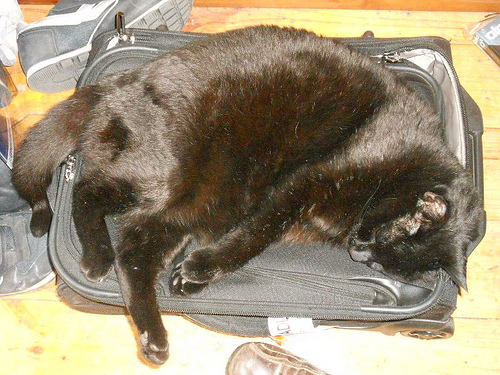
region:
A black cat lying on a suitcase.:
[11, 24, 483, 366]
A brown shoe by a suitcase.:
[225, 339, 329, 373]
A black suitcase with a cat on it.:
[46, 23, 484, 337]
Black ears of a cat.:
[418, 186, 468, 293]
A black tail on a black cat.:
[9, 83, 106, 235]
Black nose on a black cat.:
[347, 241, 372, 261]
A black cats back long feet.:
[69, 183, 171, 368]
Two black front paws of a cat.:
[169, 245, 225, 299]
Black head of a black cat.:
[348, 159, 485, 291]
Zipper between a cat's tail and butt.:
[62, 152, 76, 184]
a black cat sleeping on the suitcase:
[11, 25, 478, 366]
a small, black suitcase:
[45, 23, 488, 338]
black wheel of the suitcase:
[402, 316, 455, 340]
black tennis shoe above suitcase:
[14, 0, 196, 92]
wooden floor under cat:
[0, 0, 499, 372]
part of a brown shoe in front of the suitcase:
[224, 341, 333, 373]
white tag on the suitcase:
[266, 310, 316, 339]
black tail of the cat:
[13, 76, 105, 237]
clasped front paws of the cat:
[169, 246, 231, 293]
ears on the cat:
[419, 190, 468, 292]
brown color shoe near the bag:
[231, 333, 351, 374]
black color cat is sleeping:
[37, 53, 459, 311]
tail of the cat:
[11, 103, 69, 235]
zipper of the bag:
[115, 13, 129, 42]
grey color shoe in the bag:
[16, 0, 208, 80]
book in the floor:
[470, 10, 498, 52]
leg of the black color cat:
[83, 169, 170, 356]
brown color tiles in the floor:
[371, 7, 461, 22]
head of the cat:
[378, 155, 464, 290]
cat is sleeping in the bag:
[88, 23, 448, 288]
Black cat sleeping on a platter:
[10, 20, 459, 350]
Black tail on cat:
[0, 87, 72, 241]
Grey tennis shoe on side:
[9, 5, 106, 83]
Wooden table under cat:
[333, 4, 450, 30]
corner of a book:
[461, 13, 498, 58]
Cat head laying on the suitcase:
[334, 176, 482, 288]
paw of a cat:
[164, 248, 219, 303]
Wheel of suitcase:
[401, 315, 461, 351]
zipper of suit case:
[106, 13, 138, 36]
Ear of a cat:
[411, 182, 455, 223]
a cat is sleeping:
[73, 30, 498, 334]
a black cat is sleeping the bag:
[72, 22, 474, 316]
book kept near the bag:
[461, 23, 498, 53]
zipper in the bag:
[111, 9, 131, 43]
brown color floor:
[321, 12, 463, 37]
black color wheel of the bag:
[396, 310, 461, 342]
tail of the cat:
[20, 118, 50, 233]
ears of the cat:
[421, 189, 473, 287]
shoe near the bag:
[16, 0, 179, 80]